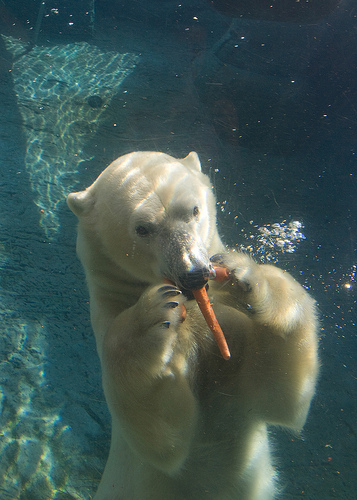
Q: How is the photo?
A: Clear.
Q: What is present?
A: A bear.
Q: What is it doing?
A: Eating.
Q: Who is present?
A: Nobody.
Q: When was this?
A: Daytime.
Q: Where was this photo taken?
A: At a zoo.